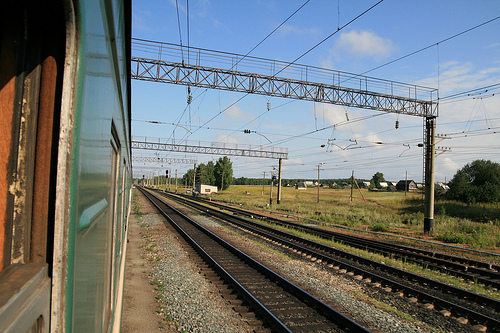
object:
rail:
[134, 183, 366, 333]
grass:
[152, 178, 500, 255]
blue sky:
[113, 0, 500, 177]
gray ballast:
[267, 262, 416, 332]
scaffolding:
[128, 34, 442, 117]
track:
[135, 185, 368, 333]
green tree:
[443, 157, 499, 204]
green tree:
[369, 180, 376, 190]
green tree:
[213, 155, 234, 191]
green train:
[1, 0, 129, 330]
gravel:
[154, 257, 156, 259]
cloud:
[328, 35, 394, 60]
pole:
[317, 165, 320, 203]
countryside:
[126, 177, 500, 333]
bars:
[131, 36, 441, 120]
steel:
[140, 192, 294, 333]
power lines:
[293, 0, 385, 63]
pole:
[421, 113, 439, 235]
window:
[106, 116, 123, 331]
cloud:
[126, 2, 497, 180]